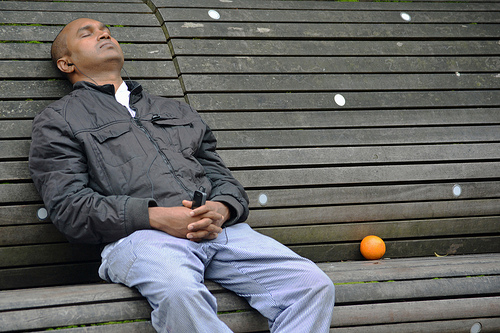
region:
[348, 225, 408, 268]
An orange on a wooden bench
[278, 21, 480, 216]
Wooden slats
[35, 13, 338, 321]
Man relaxing on a bench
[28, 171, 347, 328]
Man wearing light blue jeans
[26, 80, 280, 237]
Man wearing a gray jacket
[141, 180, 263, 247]
Man clasping a cell phone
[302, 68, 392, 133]
White dot on wooden slots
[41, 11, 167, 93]
Man with a very short haircut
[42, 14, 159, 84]
A man who looks like he's sleeping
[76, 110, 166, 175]
Pocket on a man's jacket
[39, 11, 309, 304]
man resting on bench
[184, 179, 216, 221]
cell phone in hands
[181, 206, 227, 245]
interlaced fingers of hand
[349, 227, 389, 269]
orange on bench seat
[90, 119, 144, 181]
pocket on gray jacket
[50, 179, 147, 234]
sleeve of gray jacket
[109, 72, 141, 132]
white shirt under coat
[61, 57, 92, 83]
earbud in man's ear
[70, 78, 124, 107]
upturned collar on coat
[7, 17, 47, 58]
green vegetation between wood boards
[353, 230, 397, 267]
An orange.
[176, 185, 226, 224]
A cell phone.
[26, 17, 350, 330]
A man resting on bench.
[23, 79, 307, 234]
A black jacket.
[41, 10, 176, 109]
A clean shaven man.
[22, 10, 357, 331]
A man wearing blue jeans.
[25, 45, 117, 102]
An ear phone.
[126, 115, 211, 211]
A zipper on a jacket.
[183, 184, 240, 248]
A wire connected to the cell phone.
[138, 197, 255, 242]
Man's fingers interlaced.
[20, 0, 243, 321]
this is a man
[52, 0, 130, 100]
the man is listening to music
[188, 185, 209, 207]
this is a cell phone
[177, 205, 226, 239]
the hands are crossed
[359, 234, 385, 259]
this is an orange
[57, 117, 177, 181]
the jacket is warm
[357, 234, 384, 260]
the orange is orange in color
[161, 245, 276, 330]
this is a trouser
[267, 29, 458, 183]
this is a bench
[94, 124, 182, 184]
the jacket is black in color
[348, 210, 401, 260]
A orange sitting on a bench.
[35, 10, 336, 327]
A man resting on a bench.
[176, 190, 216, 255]
A mp 3 player between two hands.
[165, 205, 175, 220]
The man has dark skin.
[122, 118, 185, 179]
A grey jacket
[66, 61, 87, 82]
A black ear bud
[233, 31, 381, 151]
The bench is made of wood.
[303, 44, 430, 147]
The wood of the bench is weathered.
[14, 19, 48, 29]
A bit of moss wedged in the bench pallets.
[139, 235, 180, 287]
The man's pants are light blue.